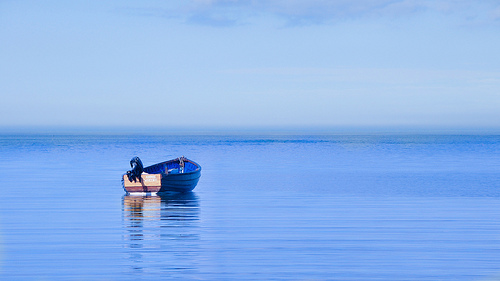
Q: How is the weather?
A: It is cloudy.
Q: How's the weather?
A: It is cloudy.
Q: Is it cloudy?
A: Yes, it is cloudy.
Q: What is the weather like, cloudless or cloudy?
A: It is cloudy.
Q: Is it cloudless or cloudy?
A: It is cloudy.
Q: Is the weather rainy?
A: No, it is cloudy.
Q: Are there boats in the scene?
A: Yes, there is a boat.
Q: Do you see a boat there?
A: Yes, there is a boat.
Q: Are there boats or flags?
A: Yes, there is a boat.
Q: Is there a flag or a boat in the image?
A: Yes, there is a boat.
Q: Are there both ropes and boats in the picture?
A: No, there is a boat but no ropes.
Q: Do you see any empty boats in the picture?
A: Yes, there is an empty boat.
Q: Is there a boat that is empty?
A: Yes, there is a boat that is empty.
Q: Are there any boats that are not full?
A: Yes, there is a empty boat.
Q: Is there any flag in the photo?
A: No, there are no flags.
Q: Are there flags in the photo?
A: No, there are no flags.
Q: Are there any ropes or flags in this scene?
A: No, there are no flags or ropes.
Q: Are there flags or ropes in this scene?
A: No, there are no flags or ropes.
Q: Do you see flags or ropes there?
A: No, there are no flags or ropes.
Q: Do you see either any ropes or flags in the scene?
A: No, there are no flags or ropes.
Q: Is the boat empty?
A: Yes, the boat is empty.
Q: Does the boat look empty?
A: Yes, the boat is empty.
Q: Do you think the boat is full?
A: No, the boat is empty.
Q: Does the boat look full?
A: No, the boat is empty.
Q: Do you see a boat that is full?
A: No, there is a boat but it is empty.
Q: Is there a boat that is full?
A: No, there is a boat but it is empty.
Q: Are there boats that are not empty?
A: No, there is a boat but it is empty.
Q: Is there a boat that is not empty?
A: No, there is a boat but it is empty.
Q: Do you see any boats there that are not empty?
A: No, there is a boat but it is empty.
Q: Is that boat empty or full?
A: The boat is empty.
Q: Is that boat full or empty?
A: The boat is empty.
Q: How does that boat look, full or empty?
A: The boat is empty.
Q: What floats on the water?
A: The boat floats on the water.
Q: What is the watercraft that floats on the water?
A: The watercraft is a boat.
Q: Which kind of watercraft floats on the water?
A: The watercraft is a boat.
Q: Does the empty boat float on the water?
A: Yes, the boat floats on the water.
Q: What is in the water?
A: The boat is in the water.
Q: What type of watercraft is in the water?
A: The watercraft is a boat.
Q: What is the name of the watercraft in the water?
A: The watercraft is a boat.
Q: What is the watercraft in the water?
A: The watercraft is a boat.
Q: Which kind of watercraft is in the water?
A: The watercraft is a boat.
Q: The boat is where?
A: The boat is in the water.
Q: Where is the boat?
A: The boat is in the water.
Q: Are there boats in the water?
A: Yes, there is a boat in the water.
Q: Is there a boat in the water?
A: Yes, there is a boat in the water.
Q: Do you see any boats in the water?
A: Yes, there is a boat in the water.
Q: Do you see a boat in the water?
A: Yes, there is a boat in the water.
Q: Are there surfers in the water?
A: No, there is a boat in the water.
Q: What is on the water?
A: The boat is on the water.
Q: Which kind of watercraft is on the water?
A: The watercraft is a boat.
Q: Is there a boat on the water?
A: Yes, there is a boat on the water.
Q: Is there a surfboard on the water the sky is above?
A: No, there is a boat on the water.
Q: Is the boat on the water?
A: Yes, the boat is on the water.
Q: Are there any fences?
A: No, there are no fences.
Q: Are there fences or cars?
A: No, there are no fences or cars.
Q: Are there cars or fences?
A: No, there are no fences or cars.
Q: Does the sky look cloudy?
A: Yes, the sky is cloudy.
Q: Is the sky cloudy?
A: Yes, the sky is cloudy.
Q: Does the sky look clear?
A: No, the sky is cloudy.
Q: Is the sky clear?
A: No, the sky is cloudy.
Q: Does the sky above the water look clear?
A: No, the sky is cloudy.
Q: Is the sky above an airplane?
A: No, the sky is above a boat.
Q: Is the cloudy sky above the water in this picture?
A: Yes, the sky is above the water.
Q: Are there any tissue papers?
A: No, there are no tissue papers.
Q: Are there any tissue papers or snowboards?
A: No, there are no tissue papers or snowboards.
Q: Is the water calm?
A: Yes, the water is calm.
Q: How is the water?
A: The water is calm.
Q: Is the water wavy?
A: No, the water is calm.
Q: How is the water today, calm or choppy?
A: The water is calm.